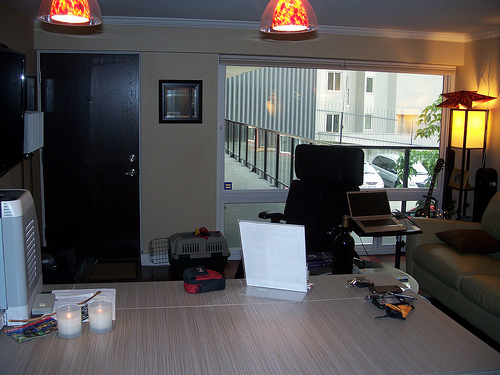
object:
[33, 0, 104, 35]
light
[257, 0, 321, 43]
light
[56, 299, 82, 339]
candle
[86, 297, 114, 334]
candle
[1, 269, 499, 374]
table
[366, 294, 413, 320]
object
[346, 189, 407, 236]
laptop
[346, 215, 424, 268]
table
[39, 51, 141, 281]
door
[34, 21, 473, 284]
wall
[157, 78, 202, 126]
mirror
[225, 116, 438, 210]
fence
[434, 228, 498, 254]
pillow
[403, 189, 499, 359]
couch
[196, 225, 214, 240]
pet carrier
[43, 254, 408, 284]
floor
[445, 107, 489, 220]
lamp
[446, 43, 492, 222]
corner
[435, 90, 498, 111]
star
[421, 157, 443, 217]
guitar neck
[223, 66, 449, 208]
window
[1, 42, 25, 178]
tv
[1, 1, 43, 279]
wall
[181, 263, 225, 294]
bag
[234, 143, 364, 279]
chair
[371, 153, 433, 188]
mini van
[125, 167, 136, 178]
door handle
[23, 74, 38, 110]
picture frame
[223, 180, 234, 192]
sign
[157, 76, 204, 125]
mirror frame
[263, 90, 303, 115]
reflection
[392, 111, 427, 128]
reflection